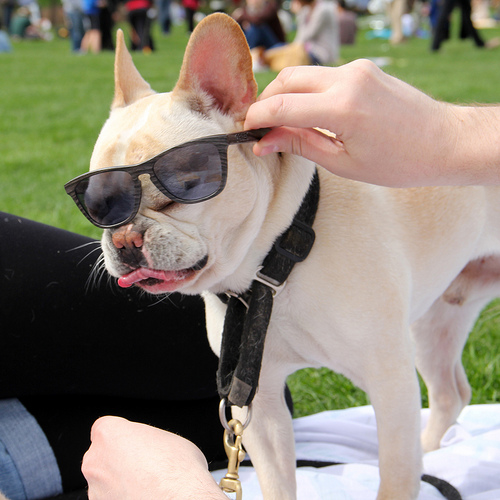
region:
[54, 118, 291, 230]
a pair of black sunglasses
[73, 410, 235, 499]
the hand of a person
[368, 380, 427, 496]
the leg of a dog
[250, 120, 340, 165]
the thumb of a person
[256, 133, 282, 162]
the thumb nail of a person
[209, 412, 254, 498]
a golden clasp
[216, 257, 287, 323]
a silver buckle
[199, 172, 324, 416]
a black dog collar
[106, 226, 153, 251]
the nose of the dog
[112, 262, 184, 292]
the tongue of the dog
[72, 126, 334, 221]
sunglasses being put on dog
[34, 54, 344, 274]
face of white dog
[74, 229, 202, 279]
nose of white dog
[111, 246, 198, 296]
tongue of white dog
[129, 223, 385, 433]
black collar on dog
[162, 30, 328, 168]
ear of white dog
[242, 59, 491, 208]
hand holding black sunglasses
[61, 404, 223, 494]
hand holding dog leash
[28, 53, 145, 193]
green grass at park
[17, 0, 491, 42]
people picnicing in the background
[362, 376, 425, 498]
a white leg of the dog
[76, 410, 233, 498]
a hand of the person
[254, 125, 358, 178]
a thumb on the person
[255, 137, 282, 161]
the thumbnail of the person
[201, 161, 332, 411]
a black collar on the dog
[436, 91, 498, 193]
the wrist of the person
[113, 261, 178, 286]
he tongue of the dog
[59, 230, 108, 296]
the whiskers of the dog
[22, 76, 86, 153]
a field with green grass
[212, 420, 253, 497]
a gold leash connector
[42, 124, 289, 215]
a pair of black sun glasses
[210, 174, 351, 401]
a black dog collar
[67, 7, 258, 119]
white ears on a dog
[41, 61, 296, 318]
a white dog with sunglasses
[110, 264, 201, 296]
a tongue of a dog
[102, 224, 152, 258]
a pink dog nose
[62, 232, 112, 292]
white whiskers on a dog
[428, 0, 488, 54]
a person in black pants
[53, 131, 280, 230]
Dog is wearing sunglasses.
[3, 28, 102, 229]
Grass is green.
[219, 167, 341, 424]
The dogs collar is black.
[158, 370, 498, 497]
The dog is on a blanket.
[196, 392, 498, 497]
The blanket is white.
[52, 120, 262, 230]
The sunglasses are black.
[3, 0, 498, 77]
People sitting in background.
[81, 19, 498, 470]
The dog is blonde.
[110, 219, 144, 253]
the dogs nose is pink.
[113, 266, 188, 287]
the dogs tongue is pink.